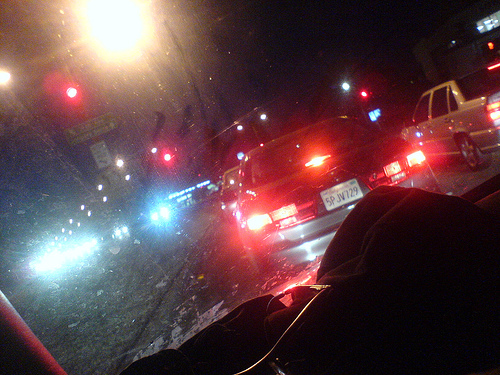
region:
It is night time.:
[12, 13, 499, 364]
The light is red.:
[243, 190, 278, 240]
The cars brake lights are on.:
[224, 133, 427, 236]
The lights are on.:
[21, 198, 198, 270]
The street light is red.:
[47, 58, 84, 109]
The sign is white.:
[83, 135, 120, 177]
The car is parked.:
[389, 78, 499, 157]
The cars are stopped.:
[174, 73, 495, 235]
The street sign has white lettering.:
[54, 110, 132, 141]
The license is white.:
[306, 175, 365, 209]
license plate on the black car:
[317, 176, 365, 216]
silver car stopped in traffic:
[399, 68, 499, 171]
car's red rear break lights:
[238, 142, 428, 243]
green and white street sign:
[65, 110, 121, 149]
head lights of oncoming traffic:
[26, 200, 174, 279]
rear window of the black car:
[241, 115, 376, 191]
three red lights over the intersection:
[61, 83, 373, 167]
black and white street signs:
[86, 143, 130, 201]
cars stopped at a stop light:
[217, 73, 499, 283]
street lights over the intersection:
[0, 9, 156, 96]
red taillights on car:
[265, 153, 438, 238]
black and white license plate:
[320, 176, 364, 215]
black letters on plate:
[319, 179, 359, 205]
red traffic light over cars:
[45, 74, 82, 112]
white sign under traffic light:
[81, 135, 106, 179]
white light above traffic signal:
[69, 6, 176, 57]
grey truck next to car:
[397, 72, 499, 174]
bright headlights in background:
[142, 191, 165, 241]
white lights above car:
[219, 99, 302, 156]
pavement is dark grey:
[50, 266, 192, 373]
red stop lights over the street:
[139, 49, 374, 175]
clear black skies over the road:
[238, 24, 340, 80]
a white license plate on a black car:
[310, 168, 365, 217]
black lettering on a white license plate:
[318, 183, 362, 205]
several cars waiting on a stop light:
[158, 64, 460, 338]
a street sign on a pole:
[53, 71, 127, 176]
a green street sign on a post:
[56, 113, 118, 147]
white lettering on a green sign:
[56, 111, 117, 146]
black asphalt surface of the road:
[451, 165, 473, 192]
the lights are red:
[143, 147, 185, 177]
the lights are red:
[253, 190, 311, 245]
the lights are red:
[400, 148, 432, 186]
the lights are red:
[45, 80, 147, 131]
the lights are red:
[225, 163, 275, 258]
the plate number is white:
[293, 170, 405, 250]